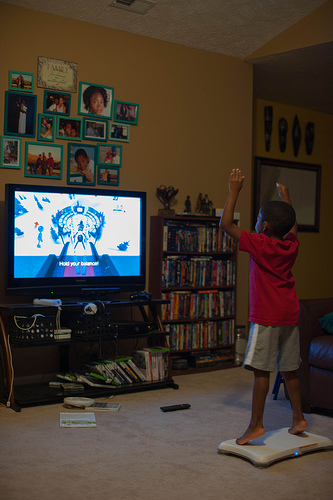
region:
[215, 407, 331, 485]
a white wii board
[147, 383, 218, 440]
a black remote on the floor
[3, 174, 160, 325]
a black flat screen tv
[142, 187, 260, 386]
a wooden bookcase with dvds on it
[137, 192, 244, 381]
a wooden bookcase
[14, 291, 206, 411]
a black tv stand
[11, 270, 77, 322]
a white wii controller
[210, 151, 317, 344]
a boy wearing a red tshirt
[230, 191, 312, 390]
a boy wearing gray shorts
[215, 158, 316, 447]
Boy playing a video game.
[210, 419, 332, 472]
Game pad on the floor.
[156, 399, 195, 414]
Remote control on the floor.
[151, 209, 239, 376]
Book shelf against the wall.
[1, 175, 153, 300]
television on the stand.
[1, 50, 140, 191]
Pictures on the wall.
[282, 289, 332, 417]
Couch beside the boy.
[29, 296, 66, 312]
White control on the stand.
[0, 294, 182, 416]
Television stand against the wall.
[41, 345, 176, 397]
Video games on the shelf.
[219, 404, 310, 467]
kid is on a white object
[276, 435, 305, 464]
a small blue light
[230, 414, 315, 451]
kid is on tippy-toes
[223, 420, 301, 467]
a small video game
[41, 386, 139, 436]
dvds on the ground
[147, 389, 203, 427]
a small black remote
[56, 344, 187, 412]
a number of dvds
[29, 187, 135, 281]
a video game on screen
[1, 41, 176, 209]
Pictures on the wall.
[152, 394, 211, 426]
Remote on the ground.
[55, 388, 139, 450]
Magazines on the ground.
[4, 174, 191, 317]
TV on the stand.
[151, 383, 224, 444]
Black remote on the floor.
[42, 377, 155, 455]
Magazines on the floor.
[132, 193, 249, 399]
Videos on the shelf.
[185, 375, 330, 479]
Boy on a platform.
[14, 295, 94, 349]
Wire on the table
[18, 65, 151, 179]
multiple green frames on a yellow wall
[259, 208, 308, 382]
boy in grey shorts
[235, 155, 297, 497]
boy on a gaming pad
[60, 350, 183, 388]
multiple video game cases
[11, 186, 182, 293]
tv with a video game on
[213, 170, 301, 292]
boy with arms in the air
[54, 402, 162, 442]
video games on the carpet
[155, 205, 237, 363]
case with many movies and game cases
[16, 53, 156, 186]
many photos of people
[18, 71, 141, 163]
Pictures on the wall.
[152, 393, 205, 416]
Remote control on the floor.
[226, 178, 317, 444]
Boy is playing a wii game.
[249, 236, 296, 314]
The shirt is red.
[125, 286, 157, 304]
Game control on the stand.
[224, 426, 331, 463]
A wii platform on the ground.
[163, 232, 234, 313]
VCR on the shelf.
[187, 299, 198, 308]
a movie on the shelf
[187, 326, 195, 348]
a movie on the shelf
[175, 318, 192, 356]
a movie on the shelf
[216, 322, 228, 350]
a movie on the shelf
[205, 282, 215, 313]
a movie on the shelf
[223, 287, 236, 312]
a movie on the shelf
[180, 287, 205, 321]
a movie on the shelf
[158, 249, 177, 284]
a movie on the shelf